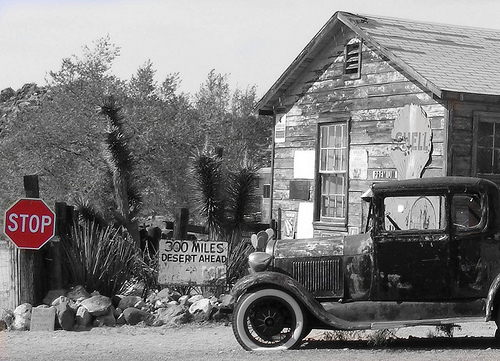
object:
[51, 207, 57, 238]
border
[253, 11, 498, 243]
building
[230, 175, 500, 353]
car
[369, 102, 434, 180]
sign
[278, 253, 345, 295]
grate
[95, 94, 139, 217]
needles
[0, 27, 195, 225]
tree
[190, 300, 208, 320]
stones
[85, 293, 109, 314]
stones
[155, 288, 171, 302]
stones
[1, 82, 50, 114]
rocks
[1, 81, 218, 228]
hill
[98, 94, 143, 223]
cactus tree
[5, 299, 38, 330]
rocks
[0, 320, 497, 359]
ground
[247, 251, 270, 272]
headlight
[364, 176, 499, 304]
driver side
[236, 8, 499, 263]
house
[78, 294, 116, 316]
rock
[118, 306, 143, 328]
rock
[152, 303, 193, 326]
rock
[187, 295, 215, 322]
rock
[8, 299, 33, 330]
rock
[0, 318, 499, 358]
road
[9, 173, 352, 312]
fence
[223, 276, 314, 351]
tire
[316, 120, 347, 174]
bars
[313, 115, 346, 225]
window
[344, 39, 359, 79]
attic vent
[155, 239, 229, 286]
desert sign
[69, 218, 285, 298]
brush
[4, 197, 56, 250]
sign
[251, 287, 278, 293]
wall